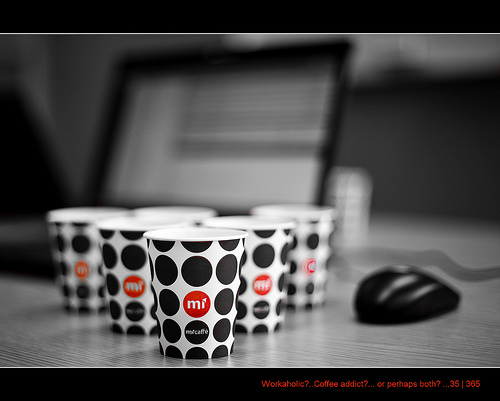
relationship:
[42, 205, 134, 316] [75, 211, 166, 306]
cups of yogurt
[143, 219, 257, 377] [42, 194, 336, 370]
cup in front of cups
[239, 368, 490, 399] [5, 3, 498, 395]
text at bottom of photograph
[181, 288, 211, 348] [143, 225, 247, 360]
coffee on front of cup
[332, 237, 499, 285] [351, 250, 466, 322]
cable behind mouse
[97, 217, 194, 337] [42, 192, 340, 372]
cup in a pattern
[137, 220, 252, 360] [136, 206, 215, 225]
cup in front of cup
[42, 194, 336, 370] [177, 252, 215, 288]
cups with polka dot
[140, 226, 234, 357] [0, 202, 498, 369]
cup on desk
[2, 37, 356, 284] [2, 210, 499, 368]
laptop on desk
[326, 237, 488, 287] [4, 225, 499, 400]
cord on desk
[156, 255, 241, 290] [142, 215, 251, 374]
dots on cup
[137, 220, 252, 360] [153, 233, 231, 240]
cup with interior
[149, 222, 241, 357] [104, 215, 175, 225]
cup with interior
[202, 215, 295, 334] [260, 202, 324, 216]
cup with interior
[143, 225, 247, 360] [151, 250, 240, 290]
cup with dots